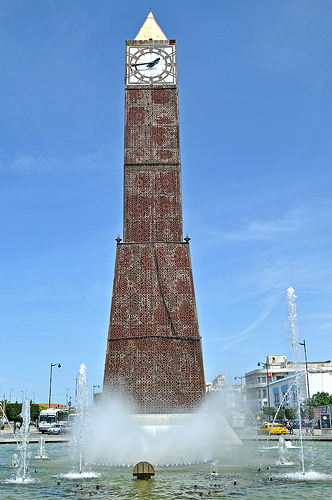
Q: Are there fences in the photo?
A: No, there are no fences.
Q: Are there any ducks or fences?
A: No, there are no fences or ducks.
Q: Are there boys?
A: No, there are no boys.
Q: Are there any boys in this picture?
A: No, there are no boys.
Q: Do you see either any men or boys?
A: No, there are no boys or men.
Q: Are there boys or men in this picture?
A: No, there are no boys or men.